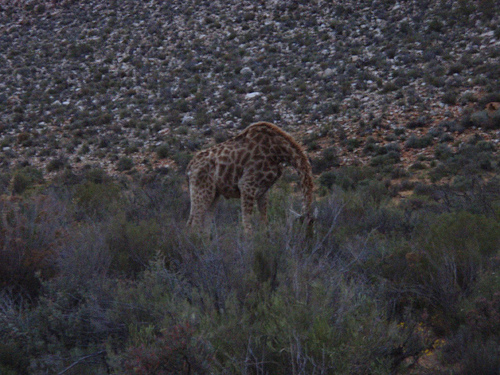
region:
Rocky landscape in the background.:
[10, 10, 484, 97]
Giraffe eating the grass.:
[174, 110, 324, 240]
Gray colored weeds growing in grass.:
[55, 213, 112, 318]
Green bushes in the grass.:
[426, 208, 496, 294]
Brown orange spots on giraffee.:
[185, 115, 320, 215]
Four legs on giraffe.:
[175, 123, 320, 240]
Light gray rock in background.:
[240, 81, 266, 99]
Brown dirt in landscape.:
[348, 129, 427, 175]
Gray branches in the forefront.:
[282, 270, 320, 373]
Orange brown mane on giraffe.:
[257, 117, 330, 223]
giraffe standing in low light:
[181, 118, 316, 259]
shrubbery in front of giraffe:
[30, 175, 475, 360]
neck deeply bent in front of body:
[255, 115, 320, 260]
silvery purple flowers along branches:
[30, 210, 361, 341]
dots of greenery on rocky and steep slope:
[71, 17, 431, 99]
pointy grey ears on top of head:
[282, 202, 322, 247]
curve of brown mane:
[235, 115, 315, 210]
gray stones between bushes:
[102, 31, 447, 111]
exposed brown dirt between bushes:
[342, 115, 477, 185]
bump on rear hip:
[191, 156, 208, 184]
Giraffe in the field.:
[175, 126, 333, 249]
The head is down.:
[288, 200, 330, 237]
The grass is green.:
[84, 188, 132, 225]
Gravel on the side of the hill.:
[67, 24, 149, 63]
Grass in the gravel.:
[306, 16, 374, 50]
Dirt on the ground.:
[382, 138, 437, 166]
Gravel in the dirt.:
[370, 125, 419, 151]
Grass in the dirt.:
[382, 123, 454, 154]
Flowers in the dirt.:
[401, 318, 457, 372]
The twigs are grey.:
[294, 225, 358, 266]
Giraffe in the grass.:
[172, 109, 335, 261]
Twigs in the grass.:
[16, 208, 111, 297]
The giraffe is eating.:
[287, 203, 332, 249]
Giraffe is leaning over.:
[174, 113, 319, 251]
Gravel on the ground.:
[160, 5, 278, 52]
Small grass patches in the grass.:
[128, 50, 194, 95]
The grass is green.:
[90, 187, 142, 255]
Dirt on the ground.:
[384, 120, 457, 168]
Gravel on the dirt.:
[384, 111, 436, 148]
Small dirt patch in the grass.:
[394, 312, 455, 369]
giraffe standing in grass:
[169, 112, 326, 269]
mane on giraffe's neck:
[247, 119, 316, 199]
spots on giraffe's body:
[178, 134, 282, 206]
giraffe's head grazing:
[288, 203, 322, 263]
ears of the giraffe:
[291, 204, 323, 229]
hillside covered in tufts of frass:
[4, 21, 487, 178]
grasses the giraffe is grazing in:
[9, 163, 496, 374]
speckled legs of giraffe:
[187, 198, 272, 233]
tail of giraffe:
[180, 161, 193, 182]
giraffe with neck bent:
[172, 106, 331, 249]